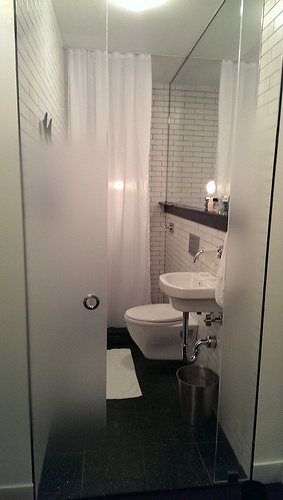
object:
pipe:
[180, 312, 188, 364]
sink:
[159, 271, 218, 300]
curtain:
[67, 47, 153, 329]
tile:
[149, 182, 162, 187]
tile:
[151, 82, 164, 90]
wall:
[0, 0, 67, 498]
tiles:
[141, 442, 212, 492]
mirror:
[166, 0, 264, 218]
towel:
[106, 346, 144, 398]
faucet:
[193, 248, 223, 263]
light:
[104, 0, 164, 17]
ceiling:
[48, 0, 262, 62]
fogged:
[21, 134, 107, 439]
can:
[176, 362, 219, 425]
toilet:
[123, 303, 197, 361]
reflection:
[0, 0, 282, 498]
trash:
[184, 372, 211, 385]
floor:
[29, 333, 282, 498]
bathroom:
[0, 1, 283, 499]